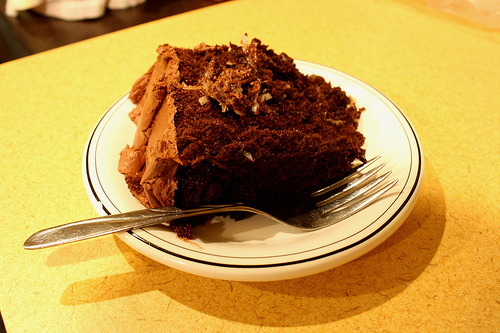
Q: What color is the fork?
A: Silver.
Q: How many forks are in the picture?
A: One.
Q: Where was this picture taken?
A: A restaurant.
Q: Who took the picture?
A: A customer.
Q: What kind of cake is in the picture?
A: Chocolate.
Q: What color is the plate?
A: White and blue.